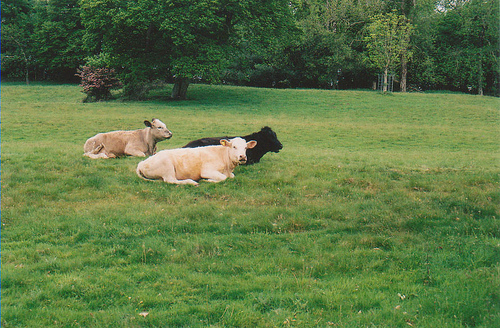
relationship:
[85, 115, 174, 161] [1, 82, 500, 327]
cow lying on grass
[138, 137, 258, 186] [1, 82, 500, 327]
cow lying on grass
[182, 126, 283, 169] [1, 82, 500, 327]
cow lying on grass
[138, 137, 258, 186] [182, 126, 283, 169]
cow near cow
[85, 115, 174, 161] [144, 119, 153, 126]
cow has ear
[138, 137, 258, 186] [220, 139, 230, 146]
cow has ear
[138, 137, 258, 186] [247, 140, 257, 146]
cow has ear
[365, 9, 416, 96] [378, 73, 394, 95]
tree protected by fence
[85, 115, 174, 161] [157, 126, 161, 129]
cow has eye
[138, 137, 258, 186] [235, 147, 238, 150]
cow has eye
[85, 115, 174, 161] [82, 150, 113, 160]
cow has tail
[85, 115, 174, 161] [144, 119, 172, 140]
cow has head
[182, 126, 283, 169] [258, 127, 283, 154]
cow has head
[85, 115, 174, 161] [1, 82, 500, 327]
cow sitting on grass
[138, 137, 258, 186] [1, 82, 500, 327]
cow sitting on grass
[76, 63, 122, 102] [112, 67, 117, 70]
bush has flower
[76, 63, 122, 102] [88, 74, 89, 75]
bush has flower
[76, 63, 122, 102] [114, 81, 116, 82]
bush has flower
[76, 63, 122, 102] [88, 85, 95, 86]
bush has flower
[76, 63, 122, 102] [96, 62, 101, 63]
bush has flower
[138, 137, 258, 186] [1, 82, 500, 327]
cow on top of grass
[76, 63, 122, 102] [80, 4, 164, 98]
bush under tree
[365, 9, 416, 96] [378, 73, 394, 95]
tree has fence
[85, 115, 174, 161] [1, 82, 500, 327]
cow in grass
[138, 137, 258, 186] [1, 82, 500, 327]
cow in grass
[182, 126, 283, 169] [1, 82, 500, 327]
cow in grass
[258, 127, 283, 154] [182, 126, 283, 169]
head of cow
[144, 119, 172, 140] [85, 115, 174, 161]
head of cow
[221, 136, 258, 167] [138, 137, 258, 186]
head of cow